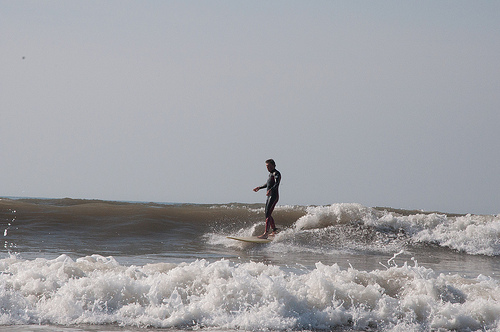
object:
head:
[267, 159, 277, 171]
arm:
[253, 175, 267, 193]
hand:
[253, 185, 261, 192]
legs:
[264, 193, 275, 238]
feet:
[261, 234, 271, 237]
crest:
[302, 207, 351, 234]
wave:
[297, 197, 358, 232]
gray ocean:
[85, 206, 178, 236]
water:
[165, 225, 226, 283]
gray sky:
[112, 27, 262, 107]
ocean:
[98, 219, 157, 261]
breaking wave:
[293, 209, 363, 245]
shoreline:
[294, 195, 386, 245]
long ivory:
[231, 228, 278, 244]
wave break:
[179, 207, 247, 254]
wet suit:
[253, 172, 281, 233]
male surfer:
[252, 159, 283, 236]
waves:
[318, 205, 367, 284]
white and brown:
[118, 214, 193, 256]